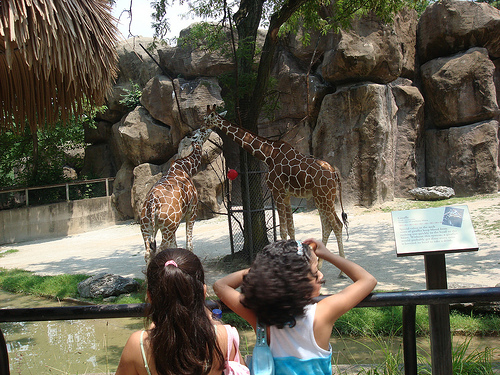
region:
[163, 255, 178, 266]
a hair tie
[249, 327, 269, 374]
a blue purse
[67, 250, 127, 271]
the shadow on the ground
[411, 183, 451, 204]
a rock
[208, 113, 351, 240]
the giraffe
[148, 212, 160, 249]
the tail of the giraffe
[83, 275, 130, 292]
a rock on the grass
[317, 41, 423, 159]
big rocks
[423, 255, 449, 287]
a metal pole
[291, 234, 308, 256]
a headband in the girls hair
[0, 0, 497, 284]
two giraffes in a zoo enclosure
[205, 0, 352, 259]
tree behind giraffe inside protective fencing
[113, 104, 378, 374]
two small girls watching giraffes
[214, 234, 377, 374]
girl leaning on black metal fence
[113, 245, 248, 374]
girl has dark hair in ponytail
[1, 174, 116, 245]
metal fence atop concrete wall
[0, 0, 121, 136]
dead palm fronds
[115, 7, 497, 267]
large rocks behind giraffes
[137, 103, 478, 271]
interpretive sign inside enclosure for giraffes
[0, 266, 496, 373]
muddy water with grassy bank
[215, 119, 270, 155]
long neck of a giraffe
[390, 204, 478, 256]
a sign about giraffes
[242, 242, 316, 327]
a girl with black curly hair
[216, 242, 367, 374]
a girl wearing a blue and white dress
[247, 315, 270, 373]
a blue purse carried by a little girl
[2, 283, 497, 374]
muddy water in the giraffe pen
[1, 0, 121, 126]
brown dry leaves on a tree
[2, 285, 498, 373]
black metal fence around the giraffe pen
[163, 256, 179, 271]
a pink pony tail holder in a little girl's hair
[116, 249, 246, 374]
a girl with a pony tail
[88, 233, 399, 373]
two little girls standing by the railing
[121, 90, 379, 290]
two giraffes standing in the enclosure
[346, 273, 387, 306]
arm on the railing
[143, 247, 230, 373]
hair pulled back in a half ponytail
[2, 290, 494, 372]
brown body of water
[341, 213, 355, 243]
long black hair on the bottom of the tail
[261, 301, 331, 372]
blue and white tank top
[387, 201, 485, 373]
informative sign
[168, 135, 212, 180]
neck is bent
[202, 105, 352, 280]
brown spots on the skin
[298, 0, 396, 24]
a dark green tree.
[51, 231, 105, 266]
a smooth white ground.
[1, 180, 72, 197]
a grey metal bar.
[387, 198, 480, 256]
a white and grey sign with printing.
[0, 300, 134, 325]
a thick black pole.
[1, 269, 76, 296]
the grass is short and green.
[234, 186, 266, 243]
a thin grey fence.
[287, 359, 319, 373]
a little girl is wearing a blue dress.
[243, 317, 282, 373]
a little girl is carrying a white shoulder bag.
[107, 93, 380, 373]
two little girls are watching the giraffes.